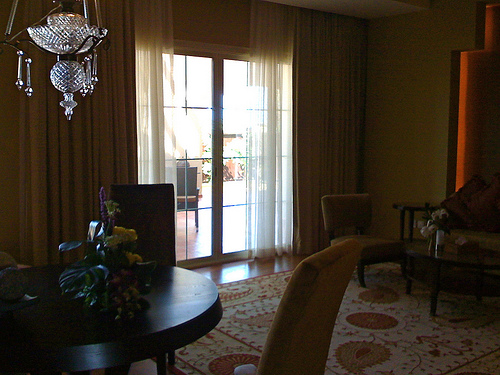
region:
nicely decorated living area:
[0, 0, 498, 374]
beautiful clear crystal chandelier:
[1, 0, 107, 120]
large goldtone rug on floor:
[148, 266, 498, 374]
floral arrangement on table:
[57, 186, 156, 321]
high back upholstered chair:
[255, 236, 360, 372]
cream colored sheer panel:
[245, 1, 295, 260]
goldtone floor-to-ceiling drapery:
[294, 3, 361, 256]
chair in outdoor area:
[175, 165, 201, 231]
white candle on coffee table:
[432, 228, 445, 253]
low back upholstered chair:
[320, 191, 403, 286]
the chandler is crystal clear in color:
[8, 9, 149, 123]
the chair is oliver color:
[322, 197, 365, 219]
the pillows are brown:
[443, 175, 490, 217]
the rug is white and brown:
[349, 312, 419, 358]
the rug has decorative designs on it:
[361, 319, 455, 363]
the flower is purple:
[81, 175, 128, 234]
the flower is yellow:
[107, 219, 143, 249]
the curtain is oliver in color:
[306, 55, 353, 126]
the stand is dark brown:
[387, 194, 435, 244]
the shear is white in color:
[241, 26, 286, 164]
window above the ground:
[156, 35, 308, 221]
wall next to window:
[378, 55, 438, 122]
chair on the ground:
[265, 246, 367, 355]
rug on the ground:
[356, 327, 423, 372]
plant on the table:
[71, 213, 159, 313]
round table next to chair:
[144, 276, 211, 336]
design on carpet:
[334, 308, 409, 373]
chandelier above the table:
[20, 23, 107, 145]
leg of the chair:
[346, 265, 383, 291]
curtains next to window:
[218, 44, 297, 149]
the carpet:
[349, 291, 416, 370]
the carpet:
[408, 293, 437, 367]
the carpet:
[397, 297, 428, 367]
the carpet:
[384, 322, 408, 370]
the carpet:
[358, 302, 394, 367]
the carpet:
[432, 271, 464, 368]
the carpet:
[394, 362, 401, 369]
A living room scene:
[9, 4, 482, 359]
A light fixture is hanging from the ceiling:
[4, 4, 129, 124]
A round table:
[4, 241, 231, 368]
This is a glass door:
[149, 31, 299, 263]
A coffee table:
[399, 229, 495, 319]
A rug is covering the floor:
[220, 264, 274, 325]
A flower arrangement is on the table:
[49, 182, 170, 333]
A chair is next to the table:
[317, 184, 438, 294]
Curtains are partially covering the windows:
[104, 0, 354, 242]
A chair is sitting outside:
[170, 156, 213, 234]